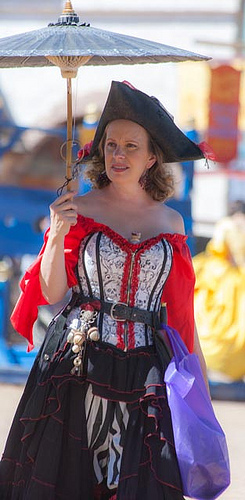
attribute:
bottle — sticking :
[129, 231, 141, 244]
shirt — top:
[7, 210, 207, 402]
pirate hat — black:
[82, 81, 213, 158]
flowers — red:
[76, 134, 96, 159]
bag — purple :
[160, 322, 237, 499]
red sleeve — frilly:
[167, 234, 194, 354]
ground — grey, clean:
[0, 373, 240, 498]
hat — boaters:
[94, 81, 178, 158]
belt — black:
[71, 292, 157, 326]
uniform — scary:
[0, 213, 196, 497]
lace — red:
[5, 374, 186, 493]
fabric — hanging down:
[8, 273, 43, 353]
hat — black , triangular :
[73, 78, 214, 169]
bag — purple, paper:
[163, 324, 229, 498]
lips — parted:
[107, 160, 131, 171]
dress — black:
[37, 222, 206, 345]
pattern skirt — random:
[50, 391, 178, 492]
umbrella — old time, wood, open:
[1, 11, 211, 213]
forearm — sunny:
[38, 234, 70, 311]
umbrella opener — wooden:
[46, 57, 89, 77]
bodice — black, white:
[71, 230, 174, 350]